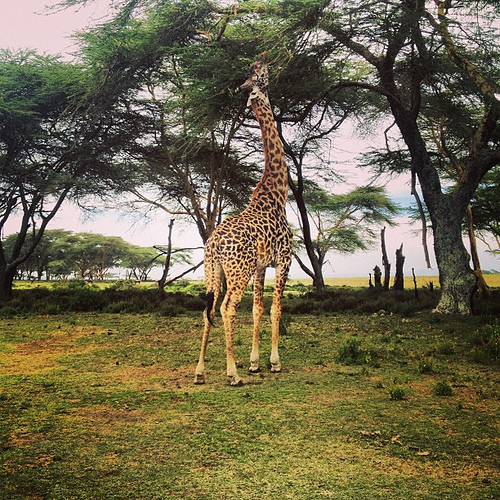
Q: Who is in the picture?
A: A Giraffe.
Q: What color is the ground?
A: Yellow and green.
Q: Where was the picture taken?
A: In a field.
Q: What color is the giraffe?
A: Yellow and brown.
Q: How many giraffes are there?
A: 1.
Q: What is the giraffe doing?
A: Standing to eat.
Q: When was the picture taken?
A: In the daytime.